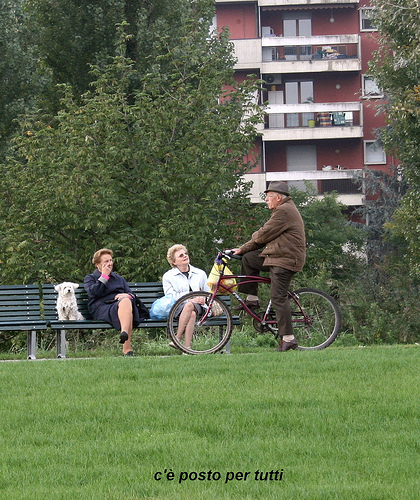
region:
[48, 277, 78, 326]
a dog on a bench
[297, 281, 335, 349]
a tire on a bike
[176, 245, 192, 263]
a woman wearing glasses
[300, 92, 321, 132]
a plant on a deck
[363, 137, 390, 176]
a window on a building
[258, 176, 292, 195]
a man wearing a hat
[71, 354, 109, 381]
grass growing on the ground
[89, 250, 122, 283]
a woman scratching her nose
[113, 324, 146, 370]
a black pair of shoes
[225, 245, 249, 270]
a handle on the bike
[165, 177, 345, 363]
an old man sits on a bike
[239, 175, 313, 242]
man has gray hair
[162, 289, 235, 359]
front wheel of bike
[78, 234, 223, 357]
two woman sit on a bench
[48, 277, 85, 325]
the dog is white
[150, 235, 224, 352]
woman has white top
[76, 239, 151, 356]
woman has short hair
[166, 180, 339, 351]
old man on a bicycle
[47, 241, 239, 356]
two ladies and a dog on a bench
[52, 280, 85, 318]
small white dog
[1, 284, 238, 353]
two green park benches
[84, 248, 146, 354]
woman on the left with her hand on her nose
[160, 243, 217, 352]
woman in the white coat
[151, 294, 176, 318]
blue bag on the bench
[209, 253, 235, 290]
yellow bag on the handlebars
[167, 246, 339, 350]
a maroon colored bicycle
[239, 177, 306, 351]
man with a brown jacket and hat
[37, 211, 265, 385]
two women on bench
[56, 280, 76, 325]
white dog next to woman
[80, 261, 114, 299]
woman has blue coat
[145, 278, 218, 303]
woman has white coat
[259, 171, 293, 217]
man has brown hat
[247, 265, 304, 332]
man has brown pants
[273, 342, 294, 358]
man has black shoes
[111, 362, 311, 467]
green and thick grass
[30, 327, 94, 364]
grey legs on benches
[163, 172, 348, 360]
person on a bicycle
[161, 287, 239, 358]
front wheel on a bicycle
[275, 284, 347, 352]
rear wheel on a bicycle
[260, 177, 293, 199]
hat on a persons head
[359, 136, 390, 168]
window on a building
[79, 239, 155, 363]
person sitting on a bench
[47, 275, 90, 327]
dog sitting on a bench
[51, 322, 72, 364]
legs on a bench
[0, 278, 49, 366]
bench on the ground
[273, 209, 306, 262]
man is wearing a brown jacket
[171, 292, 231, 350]
front tire on the bicycle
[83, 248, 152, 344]
a women sitting on the bench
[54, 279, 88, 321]
a dog on the bench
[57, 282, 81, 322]
a white dog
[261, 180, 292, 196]
hat on the man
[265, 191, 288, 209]
head of the man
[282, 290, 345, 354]
wheel of the bicycle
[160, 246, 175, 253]
hair of the woman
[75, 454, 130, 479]
the grass is growing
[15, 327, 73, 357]
legs of the bench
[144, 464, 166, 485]
c on the credit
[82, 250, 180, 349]
people on the bench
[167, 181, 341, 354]
A man sitting on a bicycle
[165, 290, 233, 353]
A tire on a bicycle